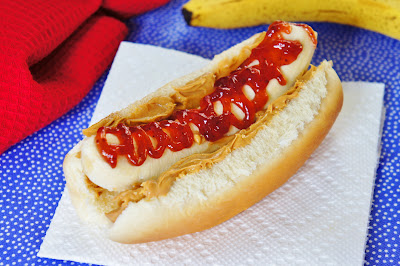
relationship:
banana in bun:
[78, 20, 319, 192] [150, 149, 334, 199]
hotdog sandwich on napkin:
[56, 20, 342, 239] [33, 38, 394, 264]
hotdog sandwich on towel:
[56, 20, 342, 239] [37, 34, 386, 264]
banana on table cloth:
[179, 0, 400, 44] [3, 4, 397, 264]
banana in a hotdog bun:
[78, 20, 319, 192] [61, 20, 344, 245]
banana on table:
[179, 0, 398, 47] [20, 29, 342, 222]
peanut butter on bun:
[78, 31, 320, 217] [61, 20, 344, 245]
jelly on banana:
[183, 67, 273, 139] [88, 139, 170, 204]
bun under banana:
[61, 20, 344, 245] [78, 20, 319, 192]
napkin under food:
[33, 38, 394, 264] [54, 14, 352, 252]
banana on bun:
[179, 0, 400, 44] [61, 20, 344, 245]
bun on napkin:
[113, 64, 347, 232] [27, 18, 357, 252]